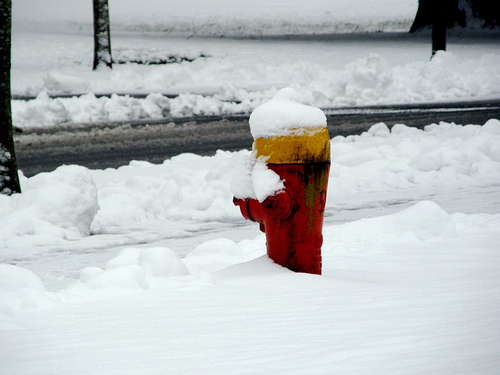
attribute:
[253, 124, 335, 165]
top — yellow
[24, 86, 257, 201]
snow — wet, slushy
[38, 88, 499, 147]
road — plowed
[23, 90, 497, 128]
sidewalk — plowed, snowy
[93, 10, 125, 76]
trunk — small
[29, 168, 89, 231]
snowball — large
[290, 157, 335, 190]
stains — dark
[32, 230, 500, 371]
snow — white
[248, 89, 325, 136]
snow — white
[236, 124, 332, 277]
fire hydrant — yellow, red, controlling